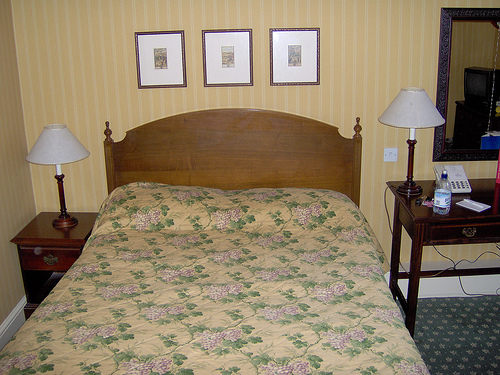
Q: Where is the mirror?
A: On the wall.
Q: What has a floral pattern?
A: The bedspread.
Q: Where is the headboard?
A: At the head of the bed.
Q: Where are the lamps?
A: On each side of the bed.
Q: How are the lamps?
A: Sitting on nightstand.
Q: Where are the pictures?
A: Above the bed.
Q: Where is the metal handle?
A: On the desk.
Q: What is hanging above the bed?
A: Three pictures.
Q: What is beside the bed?
A: A night stand.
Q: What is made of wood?
A: Headboard.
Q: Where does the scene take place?
A: Hotel room.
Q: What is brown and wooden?
A: Headboard.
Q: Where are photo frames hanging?
A: On the wall.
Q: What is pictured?
A: A bed.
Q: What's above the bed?
A: Several pictures.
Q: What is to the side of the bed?
A: A table.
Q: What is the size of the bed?
A: Queen.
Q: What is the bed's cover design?
A: Pink flowers.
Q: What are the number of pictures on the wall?
A: Three.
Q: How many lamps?
A: Two.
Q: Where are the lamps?
A: Side tables.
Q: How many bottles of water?
A: One.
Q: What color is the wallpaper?
A: Yellow.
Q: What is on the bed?
A: A blanket.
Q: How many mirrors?
A: One.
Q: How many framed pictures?
A: Three.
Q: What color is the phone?
A: White.